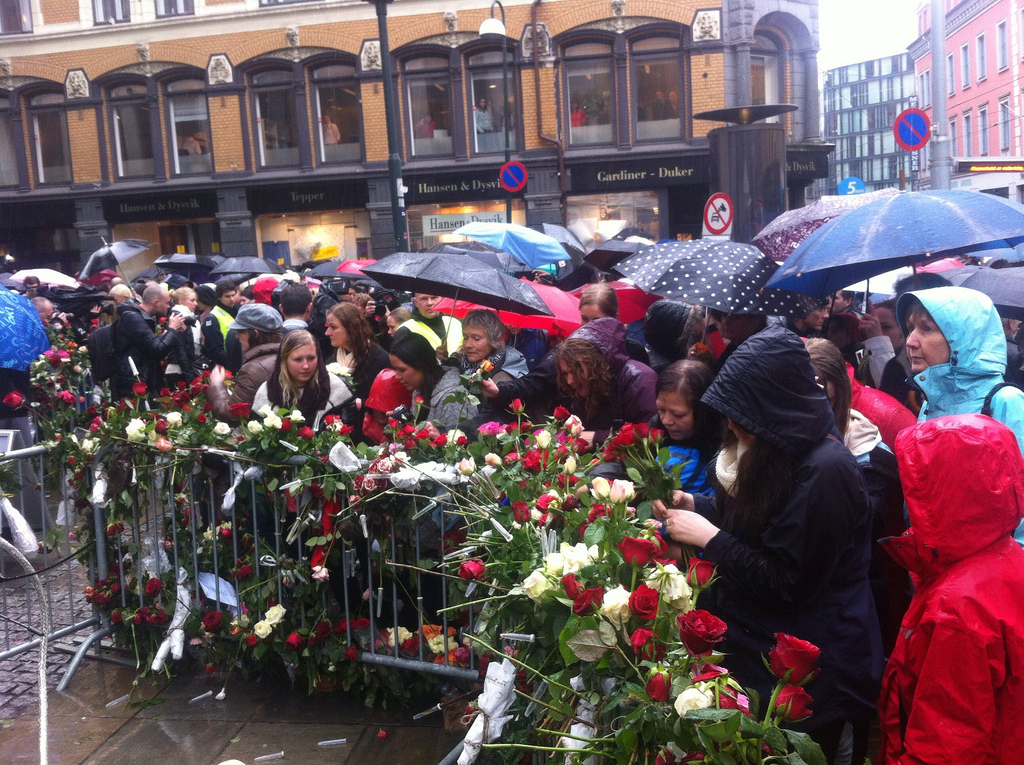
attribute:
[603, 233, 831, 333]
umbrella — black, spotted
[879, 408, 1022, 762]
coat — red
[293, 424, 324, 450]
rose — red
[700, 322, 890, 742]
raincoat — black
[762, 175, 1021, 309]
umbrella — blue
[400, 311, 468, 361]
vest — yellow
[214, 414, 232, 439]
rose — white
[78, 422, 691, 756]
railing — grey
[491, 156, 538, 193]
sign — red, blue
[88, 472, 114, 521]
flower — white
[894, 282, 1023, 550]
coat — blue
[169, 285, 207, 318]
woman — blonde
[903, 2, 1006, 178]
wall — red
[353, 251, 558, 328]
umbrella — black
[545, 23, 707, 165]
window — black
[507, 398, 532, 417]
rose — red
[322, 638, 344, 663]
leaf — green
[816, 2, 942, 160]
sky — white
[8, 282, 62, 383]
umbrella — blue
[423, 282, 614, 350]
ubrella — red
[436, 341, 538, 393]
coat — grey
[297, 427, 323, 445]
flower — red